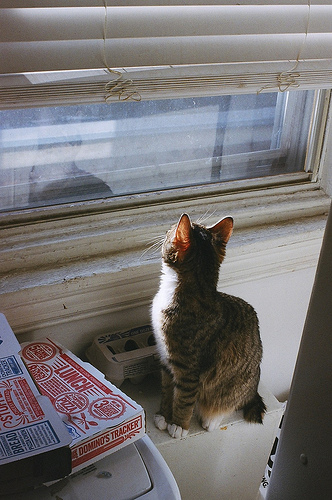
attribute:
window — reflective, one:
[0, 82, 316, 218]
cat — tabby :
[129, 214, 277, 433]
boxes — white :
[8, 306, 173, 498]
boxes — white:
[14, 333, 148, 491]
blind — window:
[0, 1, 330, 108]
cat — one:
[110, 206, 276, 432]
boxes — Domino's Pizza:
[5, 299, 152, 481]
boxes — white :
[9, 315, 159, 489]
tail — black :
[244, 402, 268, 430]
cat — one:
[141, 206, 296, 441]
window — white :
[96, 59, 328, 170]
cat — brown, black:
[142, 207, 271, 443]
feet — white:
[150, 409, 195, 450]